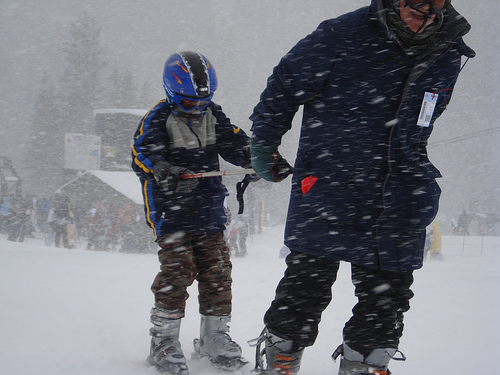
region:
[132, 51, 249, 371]
a person with a blue helmet on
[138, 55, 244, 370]
a person wearing a blue helmet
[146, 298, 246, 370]
snow boots on the person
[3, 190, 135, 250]
some people standing in the snow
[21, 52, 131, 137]
snow falling from the sky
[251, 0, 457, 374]
a person wearing a blue jacket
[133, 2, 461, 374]
two people in the snow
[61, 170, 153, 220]
a building in the distance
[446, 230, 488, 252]
a fence in the distance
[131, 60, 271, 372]
a person with blue goggles on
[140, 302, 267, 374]
Boy wearing skis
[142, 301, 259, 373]
Boy is wearing skis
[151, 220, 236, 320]
Boy wearing pants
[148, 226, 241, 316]
Boy is wearing pants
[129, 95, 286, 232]
Boy wearing a jacket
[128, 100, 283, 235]
Boy is wearing a jacket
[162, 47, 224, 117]
Boy wearing a helmet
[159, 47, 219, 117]
Boy is wearing a helmet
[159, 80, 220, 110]
Boy is wearing goggles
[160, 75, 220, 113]
Boy is wearing blue goggles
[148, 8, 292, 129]
the head of a boy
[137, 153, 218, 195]
the hand of a boy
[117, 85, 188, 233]
the arm of a boy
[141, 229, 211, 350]
the leg of a boy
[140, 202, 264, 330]
a boy wearing pants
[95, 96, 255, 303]
a boy wearing a shirt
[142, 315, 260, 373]
the feet of a boy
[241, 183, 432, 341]
the legs of a man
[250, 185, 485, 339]
a man wearing pants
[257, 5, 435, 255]
a man wearing coats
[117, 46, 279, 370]
person wearing helmet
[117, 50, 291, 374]
kid wearing blue helmet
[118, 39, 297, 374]
person wearing a pair of blade ski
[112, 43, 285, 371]
person wearing snow pants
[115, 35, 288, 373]
person on a snowy field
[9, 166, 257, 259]
bunch of people on snow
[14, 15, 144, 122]
a snowy and windy weather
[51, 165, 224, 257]
a lodging area for people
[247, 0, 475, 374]
person wearing a cloth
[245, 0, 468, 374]
person wearing pair of gloves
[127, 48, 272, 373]
Child in snow ski's on the snow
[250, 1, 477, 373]
Man on ski's pulling a child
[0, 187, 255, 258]
Group of people near a house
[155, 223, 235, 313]
Brown pants worn by child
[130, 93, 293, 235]
Blue jacket worn by kid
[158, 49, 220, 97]
Blue helmet on kid's head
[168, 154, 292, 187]
White and red rope carried by the man and child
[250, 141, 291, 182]
green gloves on the man's right hand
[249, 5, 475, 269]
Blue jacket worn by man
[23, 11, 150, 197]
Tree behind the house in the background